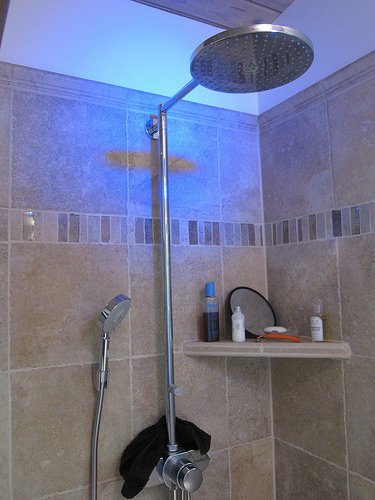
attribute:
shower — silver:
[5, 4, 364, 392]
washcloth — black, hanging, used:
[89, 402, 227, 493]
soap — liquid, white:
[222, 304, 254, 348]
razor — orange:
[251, 328, 316, 351]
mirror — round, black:
[225, 282, 285, 342]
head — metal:
[192, 23, 317, 109]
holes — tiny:
[254, 32, 260, 41]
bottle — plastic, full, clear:
[201, 282, 220, 347]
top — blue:
[201, 281, 220, 300]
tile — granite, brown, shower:
[11, 85, 134, 219]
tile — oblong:
[12, 66, 136, 119]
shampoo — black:
[203, 279, 224, 343]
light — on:
[218, 0, 327, 55]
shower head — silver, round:
[101, 294, 131, 395]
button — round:
[172, 466, 219, 500]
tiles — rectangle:
[175, 218, 270, 251]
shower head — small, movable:
[95, 293, 134, 360]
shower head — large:
[189, 23, 319, 100]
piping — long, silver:
[144, 101, 192, 451]